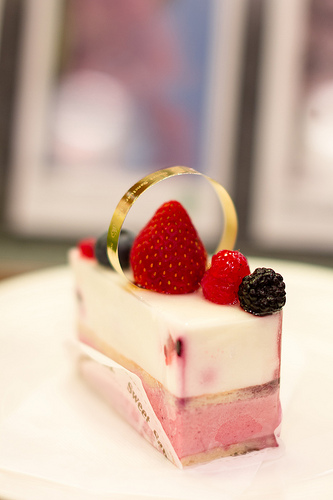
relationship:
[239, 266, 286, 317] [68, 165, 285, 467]
blackberry on cake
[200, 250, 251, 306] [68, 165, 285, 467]
rasbperry on cake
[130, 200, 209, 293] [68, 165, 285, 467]
stawberry on cake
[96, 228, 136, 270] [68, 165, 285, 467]
blueberry on cake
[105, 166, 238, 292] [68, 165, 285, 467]
gold ring on cake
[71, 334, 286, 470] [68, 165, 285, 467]
paper under cake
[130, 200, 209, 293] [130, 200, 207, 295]
stawberry has seeds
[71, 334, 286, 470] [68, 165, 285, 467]
paper underneath cake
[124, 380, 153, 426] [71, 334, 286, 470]
sweet on paper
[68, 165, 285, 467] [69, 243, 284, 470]
cake has edges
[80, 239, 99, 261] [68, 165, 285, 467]
cherry on cake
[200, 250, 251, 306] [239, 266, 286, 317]
rasbperry next to a blackberry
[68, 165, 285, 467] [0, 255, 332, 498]
cake on plate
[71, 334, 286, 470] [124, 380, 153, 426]
paper has word sweet